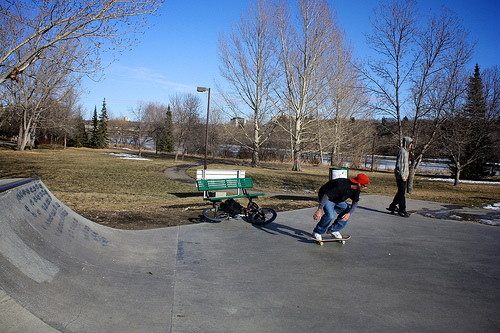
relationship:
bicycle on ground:
[203, 201, 280, 228] [86, 164, 497, 328]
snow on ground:
[428, 170, 496, 237] [86, 164, 497, 328]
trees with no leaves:
[0, 4, 498, 192] [246, 6, 456, 142]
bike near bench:
[203, 201, 280, 228] [198, 180, 267, 197]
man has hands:
[315, 174, 369, 240] [315, 192, 365, 229]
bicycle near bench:
[203, 201, 280, 228] [198, 180, 267, 197]